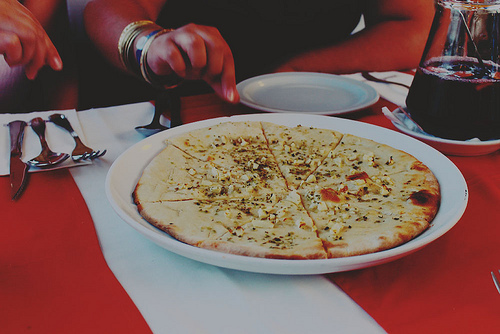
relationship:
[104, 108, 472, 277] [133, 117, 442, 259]
plate has food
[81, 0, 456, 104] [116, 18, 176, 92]
person wearing bracelets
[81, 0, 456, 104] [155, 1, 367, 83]
person wearing shirt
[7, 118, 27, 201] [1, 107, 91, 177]
utensil on napkin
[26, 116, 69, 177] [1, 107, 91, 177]
utensil on napkin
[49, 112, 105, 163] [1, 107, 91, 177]
utensil on napkin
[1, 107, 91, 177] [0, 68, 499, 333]
napkin on table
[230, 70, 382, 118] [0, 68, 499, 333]
plate on table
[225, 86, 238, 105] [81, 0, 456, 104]
fingernail of person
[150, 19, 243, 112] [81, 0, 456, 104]
hand of person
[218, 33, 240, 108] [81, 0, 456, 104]
finger of person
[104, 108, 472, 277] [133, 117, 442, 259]
plate of food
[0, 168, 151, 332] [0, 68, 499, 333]
placemat on table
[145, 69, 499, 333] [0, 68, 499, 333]
placemat on table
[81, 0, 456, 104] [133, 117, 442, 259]
person reaching for food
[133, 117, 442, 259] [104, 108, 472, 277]
food on plate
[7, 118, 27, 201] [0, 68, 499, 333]
utensil on table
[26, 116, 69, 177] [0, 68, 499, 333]
utensil on table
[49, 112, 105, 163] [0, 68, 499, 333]
utensil on table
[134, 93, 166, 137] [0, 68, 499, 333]
utensil on table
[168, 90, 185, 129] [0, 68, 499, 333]
utensil on table